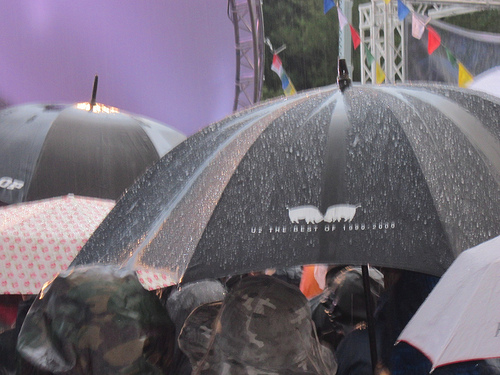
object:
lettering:
[249, 221, 399, 236]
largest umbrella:
[65, 57, 500, 374]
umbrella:
[0, 193, 179, 296]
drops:
[280, 143, 295, 156]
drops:
[445, 188, 461, 198]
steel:
[386, 34, 396, 72]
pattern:
[52, 242, 62, 250]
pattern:
[43, 253, 53, 261]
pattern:
[21, 280, 30, 287]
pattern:
[24, 236, 31, 243]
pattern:
[8, 280, 20, 287]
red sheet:
[425, 27, 440, 56]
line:
[396, 0, 476, 82]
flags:
[452, 59, 477, 87]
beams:
[355, 2, 410, 80]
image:
[251, 202, 394, 235]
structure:
[360, 0, 495, 85]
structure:
[334, 0, 354, 83]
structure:
[226, 0, 271, 113]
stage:
[1, 1, 500, 136]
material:
[69, 82, 499, 290]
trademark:
[283, 203, 365, 226]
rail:
[244, 0, 258, 106]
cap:
[16, 263, 191, 373]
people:
[176, 272, 338, 374]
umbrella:
[60, 58, 500, 375]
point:
[333, 57, 351, 88]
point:
[87, 74, 99, 106]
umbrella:
[391, 236, 499, 374]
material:
[346, 24, 364, 51]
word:
[248, 226, 265, 233]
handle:
[360, 265, 378, 374]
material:
[425, 27, 440, 52]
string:
[327, 0, 394, 82]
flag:
[361, 41, 373, 66]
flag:
[372, 62, 387, 83]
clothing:
[300, 261, 329, 301]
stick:
[86, 76, 100, 106]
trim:
[399, 334, 479, 373]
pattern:
[86, 222, 93, 228]